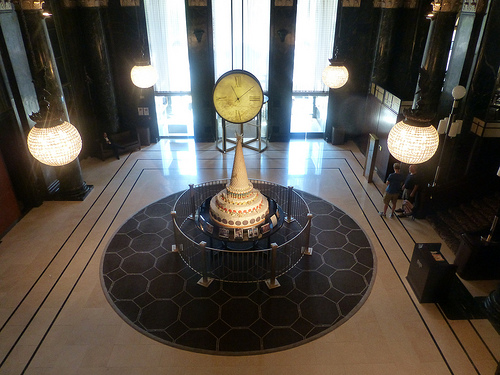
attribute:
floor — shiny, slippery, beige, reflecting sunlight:
[1, 124, 500, 373]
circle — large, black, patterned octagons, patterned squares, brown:
[101, 179, 380, 353]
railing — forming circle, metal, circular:
[168, 176, 314, 283]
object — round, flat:
[207, 184, 270, 227]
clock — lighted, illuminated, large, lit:
[212, 70, 267, 124]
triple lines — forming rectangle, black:
[2, 146, 499, 374]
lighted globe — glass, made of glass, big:
[24, 124, 87, 165]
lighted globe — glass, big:
[124, 58, 161, 89]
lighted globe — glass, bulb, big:
[320, 58, 349, 91]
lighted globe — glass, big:
[387, 114, 440, 164]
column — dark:
[18, 2, 94, 202]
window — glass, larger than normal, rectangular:
[145, 2, 197, 139]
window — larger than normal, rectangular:
[289, 2, 341, 141]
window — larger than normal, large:
[211, 2, 270, 143]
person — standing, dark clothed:
[377, 164, 404, 218]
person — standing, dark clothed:
[398, 165, 419, 220]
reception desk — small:
[406, 241, 456, 304]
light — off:
[451, 87, 467, 99]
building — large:
[1, 1, 500, 373]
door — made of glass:
[1, 146, 26, 233]